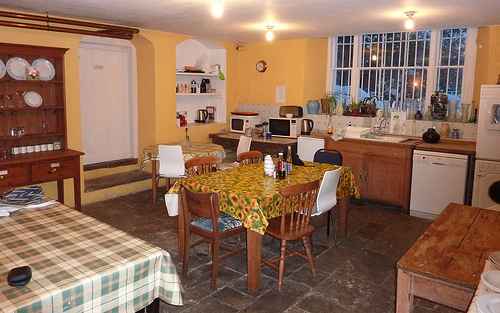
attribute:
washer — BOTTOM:
[396, 134, 466, 225]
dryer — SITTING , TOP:
[470, 77, 498, 159]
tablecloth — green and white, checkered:
[1, 163, 190, 303]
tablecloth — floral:
[196, 146, 291, 208]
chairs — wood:
[261, 169, 338, 269]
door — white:
[78, 34, 138, 167]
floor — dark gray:
[69, 182, 469, 312]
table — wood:
[376, 189, 498, 306]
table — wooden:
[387, 198, 497, 310]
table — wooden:
[162, 156, 357, 295]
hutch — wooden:
[2, 36, 84, 210]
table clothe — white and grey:
[1, 200, 185, 312]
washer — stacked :
[477, 87, 498, 157]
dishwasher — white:
[405, 148, 467, 207]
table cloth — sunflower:
[161, 152, 366, 232]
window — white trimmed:
[326, 24, 467, 99]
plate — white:
[31, 58, 57, 84]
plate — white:
[6, 56, 31, 80]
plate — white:
[0, 57, 10, 78]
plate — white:
[22, 91, 42, 107]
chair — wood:
[264, 176, 319, 290]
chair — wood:
[177, 182, 245, 290]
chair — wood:
[182, 155, 222, 177]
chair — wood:
[233, 147, 261, 164]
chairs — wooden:
[165, 141, 367, 284]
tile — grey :
[340, 254, 391, 289]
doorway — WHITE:
[16, 36, 146, 184]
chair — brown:
[171, 185, 250, 292]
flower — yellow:
[225, 193, 242, 210]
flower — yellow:
[249, 209, 261, 222]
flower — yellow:
[234, 210, 245, 224]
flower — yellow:
[198, 185, 210, 191]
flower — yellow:
[185, 178, 204, 192]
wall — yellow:
[2, 4, 243, 204]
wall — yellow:
[230, 19, 499, 136]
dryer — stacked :
[462, 158, 484, 206]